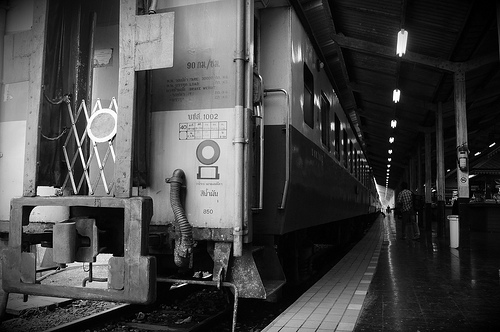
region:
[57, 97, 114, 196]
The small gate on the back of the train.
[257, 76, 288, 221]
The handrails on the side of the train.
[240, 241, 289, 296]
The step on the side of the train.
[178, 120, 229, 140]
The chart design on the back of the train.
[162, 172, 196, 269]
The black pipe on the back of the train under the chart.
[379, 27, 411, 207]
The lights on the ceiling.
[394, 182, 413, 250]
The man on the platform in a plaid shirt.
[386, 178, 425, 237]
man at the platform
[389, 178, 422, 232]
man at the platform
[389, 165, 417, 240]
man at the platform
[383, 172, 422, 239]
man at the platform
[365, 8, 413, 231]
row of lights on the ceiling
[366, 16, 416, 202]
row of lights on the ceiling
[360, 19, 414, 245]
row of lights on the ceiling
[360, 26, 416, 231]
row of lights on the ceiling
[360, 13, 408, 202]
row of lights on the ceiling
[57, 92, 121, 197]
The small gate on the back of the train.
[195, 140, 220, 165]
The circle design on the back of the train.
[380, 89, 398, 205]
The lights on the ceiling.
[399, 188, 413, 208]
The plaid shirt the person on the platform is wearing.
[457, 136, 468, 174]
The fire extinguisher on the post.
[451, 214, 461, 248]
The white trash can on the platform.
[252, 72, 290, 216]
The hand rails above the step on the side of the train.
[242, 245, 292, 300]
The step on the side of the train.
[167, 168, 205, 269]
The black pipe on the back of the train.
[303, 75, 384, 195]
The windows on the side of the train.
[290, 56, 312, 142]
Small window on a train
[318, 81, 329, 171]
Small window on a train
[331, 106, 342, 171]
Small window on a train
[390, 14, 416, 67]
Small light on the ceiling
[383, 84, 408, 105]
Small light on the ceiling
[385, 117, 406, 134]
Small light on the ceiling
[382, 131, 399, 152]
Small light on the ceiling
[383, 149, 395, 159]
Small light on the ceiling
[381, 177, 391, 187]
Small light on the ceiling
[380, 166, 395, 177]
Small light on the ceiling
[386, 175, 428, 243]
A man walking through the hallway.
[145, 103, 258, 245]
A very old electrical system in a building is displayed.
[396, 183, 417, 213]
The man has on a plaid shirt.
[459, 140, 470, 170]
A fire extinguisher is hanging from a wall post.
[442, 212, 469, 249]
A white trashcan is behind a pole.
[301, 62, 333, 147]
The wall has several windows of the same shape.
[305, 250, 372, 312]
The floor has some white tile on it.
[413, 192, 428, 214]
The man is carrying a backpack.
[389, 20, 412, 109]
There are several tube lights that are in the ceiling.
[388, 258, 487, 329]
The floor has a different color tile than white.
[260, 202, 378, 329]
the tile surface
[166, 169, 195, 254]
a coil hose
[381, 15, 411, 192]
the lights in the ceiling